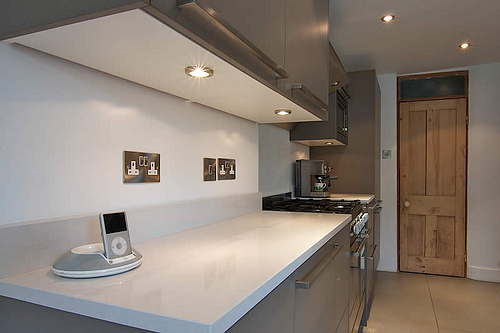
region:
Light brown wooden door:
[393, 100, 469, 276]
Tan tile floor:
[365, 270, 495, 325]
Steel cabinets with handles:
[150, 0, 322, 115]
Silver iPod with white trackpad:
[95, 210, 130, 257]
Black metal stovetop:
[262, 190, 352, 217]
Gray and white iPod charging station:
[50, 207, 140, 272]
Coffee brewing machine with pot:
[286, 156, 333, 196]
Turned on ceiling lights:
[372, 6, 474, 56]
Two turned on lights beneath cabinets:
[175, 60, 295, 120]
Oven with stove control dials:
[348, 208, 374, 329]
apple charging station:
[50, 209, 144, 281]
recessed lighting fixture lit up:
[186, 63, 216, 80]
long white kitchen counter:
[0, 192, 355, 332]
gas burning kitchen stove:
[259, 190, 370, 332]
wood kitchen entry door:
[392, 99, 471, 278]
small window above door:
[394, 66, 475, 98]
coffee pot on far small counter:
[291, 157, 336, 199]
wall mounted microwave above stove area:
[289, 89, 350, 149]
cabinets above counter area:
[1, 1, 331, 123]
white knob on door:
[401, 198, 408, 208]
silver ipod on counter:
[98, 208, 132, 257]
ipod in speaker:
[51, 240, 145, 277]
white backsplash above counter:
[1, 192, 261, 278]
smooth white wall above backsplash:
[1, 45, 260, 225]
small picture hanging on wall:
[122, 150, 161, 183]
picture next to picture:
[218, 156, 238, 179]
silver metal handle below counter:
[295, 240, 349, 286]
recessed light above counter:
[188, 65, 211, 81]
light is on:
[276, 109, 293, 117]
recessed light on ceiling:
[381, 15, 395, 23]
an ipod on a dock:
[21, 150, 217, 319]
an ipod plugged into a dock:
[2, 136, 179, 312]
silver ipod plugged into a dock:
[5, 158, 163, 315]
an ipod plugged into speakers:
[3, 158, 208, 329]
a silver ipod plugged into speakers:
[54, 188, 131, 291]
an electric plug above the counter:
[62, 105, 201, 207]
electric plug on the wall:
[121, 146, 176, 189]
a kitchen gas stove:
[226, 157, 404, 332]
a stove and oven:
[247, 165, 440, 316]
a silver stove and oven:
[264, 140, 418, 325]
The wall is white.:
[1, 39, 498, 284]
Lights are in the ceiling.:
[381, 13, 471, 52]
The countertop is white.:
[1, 193, 351, 331]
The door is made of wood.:
[394, 73, 471, 278]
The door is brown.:
[394, 71, 468, 278]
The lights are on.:
[383, 14, 471, 51]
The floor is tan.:
[361, 268, 498, 331]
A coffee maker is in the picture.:
[291, 156, 341, 196]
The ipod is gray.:
[98, 208, 133, 264]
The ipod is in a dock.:
[48, 209, 144, 279]